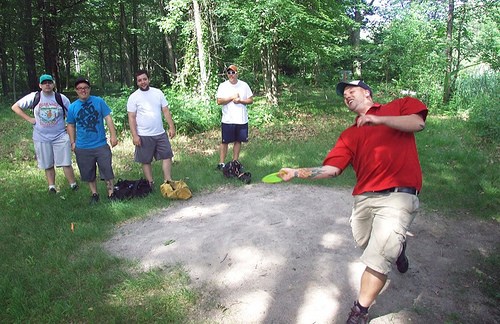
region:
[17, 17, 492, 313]
Photo taken during the day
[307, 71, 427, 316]
Man on the right in red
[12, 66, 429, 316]
People playing disc golf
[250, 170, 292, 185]
Green disk in the right hand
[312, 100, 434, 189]
Red shirt on the man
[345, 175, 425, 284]
Khaki shorts on the man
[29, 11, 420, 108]
Green leaves on the trees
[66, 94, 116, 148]
Blue shirt on the man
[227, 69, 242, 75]
Sunglasses on the man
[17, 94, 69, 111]
Backpack straps over the shoulders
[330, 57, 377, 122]
man has black cap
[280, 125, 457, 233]
man has red shirt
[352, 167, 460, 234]
man has black belt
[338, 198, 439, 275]
man has grey shorts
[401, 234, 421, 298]
man has black shoes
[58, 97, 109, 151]
blue and black shirt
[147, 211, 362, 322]
light grey starting ground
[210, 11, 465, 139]
green trees in background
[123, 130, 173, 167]
man has dark grey shorts and white shirt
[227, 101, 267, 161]
man has blue shorts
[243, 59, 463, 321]
he is tossing the flying disc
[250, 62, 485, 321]
he is about to toss the frisbee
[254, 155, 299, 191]
the frisbee is neon green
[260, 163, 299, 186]
the flying disk is neon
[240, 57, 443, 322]
he is standing on a patch of dirt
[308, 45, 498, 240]
he is wearing a red polo shirt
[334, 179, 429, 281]
he is wearing white cargo shorts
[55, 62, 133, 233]
he is wearing a blue tee shirt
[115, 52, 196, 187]
he is wearing a plain white tee shirt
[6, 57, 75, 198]
he is wearing a bright blue cap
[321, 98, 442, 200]
the shirt is red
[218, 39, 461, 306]
man is throwing the frisbee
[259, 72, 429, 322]
Man throwing green frisbee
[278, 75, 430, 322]
Man in red polo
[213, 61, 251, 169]
Man in white shirt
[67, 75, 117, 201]
Man in blue tee shirt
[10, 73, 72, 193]
Man wearing backpack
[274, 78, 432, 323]
Man with arm tatoos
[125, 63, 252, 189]
Two men in shorts and white tee shirts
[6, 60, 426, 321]
Four men watching man throw frisbee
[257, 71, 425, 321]
Man tossing green frisbee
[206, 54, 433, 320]
Man watching man throw frisbee